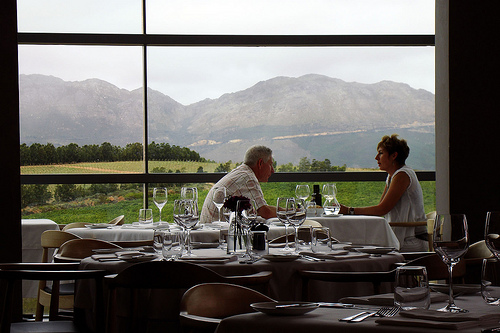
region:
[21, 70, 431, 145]
A mountain in the background.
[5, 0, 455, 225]
A large window.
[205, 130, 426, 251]
A couple having dinner.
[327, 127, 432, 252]
The woman has short hair.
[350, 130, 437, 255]
The woman is wearing a white, sleeveless shirt.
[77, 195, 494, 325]
Tables that have been set.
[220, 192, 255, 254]
A flower is in the glass vase.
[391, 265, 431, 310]
A turned over glass.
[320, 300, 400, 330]
Silverware on the table.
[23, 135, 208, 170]
A forest.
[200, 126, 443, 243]
couple talking at a table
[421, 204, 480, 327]
empty wine glass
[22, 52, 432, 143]
mountainside in the distances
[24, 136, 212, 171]
green trees on a hillside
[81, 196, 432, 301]
table set for formal meal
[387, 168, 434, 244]
adult ladies white blouse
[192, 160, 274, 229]
adult males plaid shirt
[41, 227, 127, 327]
empty seating at a table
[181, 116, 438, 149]
roadway on distance mountainside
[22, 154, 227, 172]
new crop growing on hillside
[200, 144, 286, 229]
the man is sitting at a table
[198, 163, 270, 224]
the man is wearing a short sleeve shirt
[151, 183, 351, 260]
wine glasses are seen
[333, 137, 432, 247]
the woman is sitting at the table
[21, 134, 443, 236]
a vast field of green is seen outdoors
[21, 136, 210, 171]
a group of trees is seen in the distance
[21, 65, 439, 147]
a mountain range is seen in the distance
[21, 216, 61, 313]
the tablecloth is white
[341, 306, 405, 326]
a fork is seen in the front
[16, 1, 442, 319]
the window shows daylight outside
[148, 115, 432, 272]
People dining in front of the mountains,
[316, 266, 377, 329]
Silverware on the table.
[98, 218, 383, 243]
White table cloth on the table.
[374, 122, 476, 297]
Women in a white blouse.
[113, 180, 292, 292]
Wine glasses on the table tops.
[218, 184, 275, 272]
Flowers placed on the tables center.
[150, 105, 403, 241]
Couple eating in front of the window.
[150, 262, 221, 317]
Chairs that are around the table.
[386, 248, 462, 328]
Water glass on the table.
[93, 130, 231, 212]
Grape vines in the field.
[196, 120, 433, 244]
An older couple enjoying a meal at a restaurant with a mountain view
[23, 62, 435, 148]
huge mountains in the distance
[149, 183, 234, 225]
several empty wine glasses at a table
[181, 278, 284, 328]
a low round backed chair at a table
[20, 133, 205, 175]
a long row of green trees in the distance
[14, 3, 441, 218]
a very large window for a nice view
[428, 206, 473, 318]
a tall empty wine glass on a table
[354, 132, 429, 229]
a woman with brown curly hair sitting at the table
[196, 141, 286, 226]
a man with grey hair hunched over the table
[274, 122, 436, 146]
a road leading up the mountain in the distance